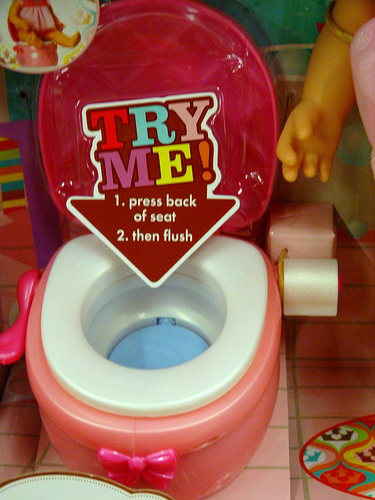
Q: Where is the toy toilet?
A: On the shelf.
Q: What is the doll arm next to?
A: The toilet.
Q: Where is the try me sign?
A: On the toilet bowl.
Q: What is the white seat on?
A: The toilet bowl.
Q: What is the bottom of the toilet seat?
A: A pink bow.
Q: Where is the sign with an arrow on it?
A: On top of the toilet seat.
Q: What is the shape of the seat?
A: Circle.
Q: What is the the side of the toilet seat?
A: Toilet paper.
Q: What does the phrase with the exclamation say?
A: Try me.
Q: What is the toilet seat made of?
A: Plastic.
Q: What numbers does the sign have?
A: 1, 2.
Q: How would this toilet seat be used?
A: As a toy.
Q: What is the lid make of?
A: Plastic.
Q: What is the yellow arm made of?
A: Plastic.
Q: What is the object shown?
A: A baby toilet.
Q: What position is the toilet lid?
A: Open.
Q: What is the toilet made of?
A: Plastic.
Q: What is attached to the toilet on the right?
A: A toilet paper roll.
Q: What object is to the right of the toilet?
A: A baby doll's arm.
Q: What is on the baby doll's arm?
A: A bracelet.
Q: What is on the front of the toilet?
A: A pink bow.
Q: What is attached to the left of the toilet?
A: A pink handle.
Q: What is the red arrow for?
A: Instructions for demonstration.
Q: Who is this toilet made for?
A: A doll.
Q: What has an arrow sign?
A: The toilet lid.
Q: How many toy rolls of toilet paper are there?
A: One.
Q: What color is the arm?
A: Yellow.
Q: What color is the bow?
A: Pink.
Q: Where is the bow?
A: Outside of the toilet bowl.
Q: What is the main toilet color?
A: Light pink.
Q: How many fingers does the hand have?
A: Five.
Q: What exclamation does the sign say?
A: TRY ME.